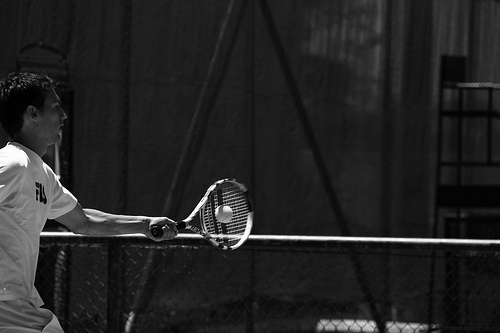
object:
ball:
[215, 205, 233, 224]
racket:
[151, 178, 256, 251]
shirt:
[1, 141, 78, 304]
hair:
[0, 72, 59, 140]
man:
[0, 71, 180, 333]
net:
[37, 231, 500, 333]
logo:
[35, 181, 47, 204]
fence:
[38, 232, 500, 333]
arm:
[52, 175, 140, 236]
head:
[0, 70, 67, 150]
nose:
[60, 108, 68, 120]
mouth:
[56, 123, 64, 133]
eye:
[54, 104, 60, 108]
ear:
[26, 105, 38, 121]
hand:
[144, 216, 179, 242]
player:
[0, 72, 177, 333]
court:
[0, 70, 500, 333]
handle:
[151, 220, 186, 236]